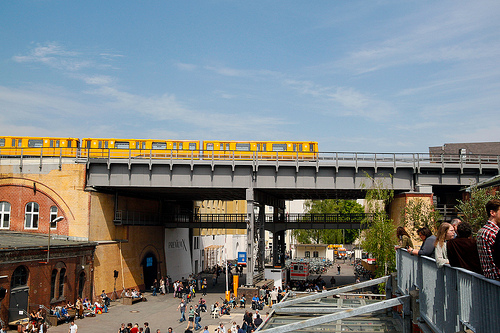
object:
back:
[292, 264, 303, 277]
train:
[0, 136, 319, 161]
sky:
[249, 86, 498, 138]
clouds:
[1, 41, 495, 137]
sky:
[9, 5, 167, 49]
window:
[115, 141, 130, 149]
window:
[293, 144, 297, 151]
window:
[263, 144, 266, 151]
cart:
[200, 140, 319, 161]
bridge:
[83, 156, 409, 198]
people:
[177, 282, 185, 298]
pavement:
[74, 279, 238, 331]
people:
[394, 227, 414, 252]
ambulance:
[290, 262, 311, 282]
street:
[279, 252, 358, 292]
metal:
[244, 188, 266, 283]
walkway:
[115, 214, 388, 229]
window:
[50, 206, 58, 229]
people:
[132, 289, 142, 299]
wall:
[163, 230, 196, 278]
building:
[1, 162, 196, 310]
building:
[423, 141, 498, 158]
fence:
[395, 245, 497, 333]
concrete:
[81, 304, 185, 333]